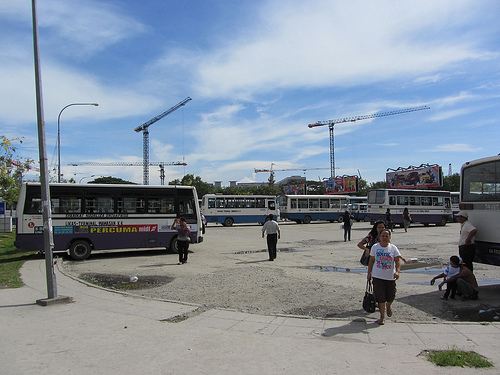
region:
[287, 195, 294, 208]
window on side of bus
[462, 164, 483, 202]
window on side of bus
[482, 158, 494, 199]
window on side of bus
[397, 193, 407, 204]
window on side of bus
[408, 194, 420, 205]
window on side of bus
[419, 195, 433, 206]
window on side of bus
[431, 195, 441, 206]
window on side of bus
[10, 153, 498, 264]
busses parked in lot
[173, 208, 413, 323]
people walking in parking lot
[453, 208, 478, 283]
person standing behind bus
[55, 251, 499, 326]
curb is curved and broken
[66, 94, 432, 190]
large boom cranes above busses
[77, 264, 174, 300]
dried up water spot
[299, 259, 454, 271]
puddle of water by squaters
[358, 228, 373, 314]
two large purses being carried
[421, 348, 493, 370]
small patch of grass in sidewalk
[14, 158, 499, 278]
buses in a parking lot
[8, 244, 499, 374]
sidewalk along parking lot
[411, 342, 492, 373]
grass patch on sidewalk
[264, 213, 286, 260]
man wearing black pants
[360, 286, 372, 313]
black purse woman is carrying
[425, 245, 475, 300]
person kneeling down with child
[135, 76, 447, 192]
construction cranes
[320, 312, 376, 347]
shadow of the woman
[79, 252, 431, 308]
puddles of water in the parking lot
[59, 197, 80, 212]
window on side of bus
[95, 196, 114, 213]
window on side of bus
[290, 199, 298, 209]
window on side of bus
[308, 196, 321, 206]
window on side of bus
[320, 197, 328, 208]
window on side of bus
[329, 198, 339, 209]
window on side of bus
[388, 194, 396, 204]
window on side of bus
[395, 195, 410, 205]
window on side of bus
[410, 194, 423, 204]
window on side of bus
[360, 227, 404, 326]
person carrying a purse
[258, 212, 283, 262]
walking man wearing white shirt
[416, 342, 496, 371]
square of grass in a sidewalk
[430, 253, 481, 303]
man behind a young boy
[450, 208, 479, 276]
man standing with his hands on his hips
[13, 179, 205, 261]
white and grey bus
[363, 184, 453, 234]
two people walking near a bus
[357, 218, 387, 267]
woman holding a purse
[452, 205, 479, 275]
man wearing a white hat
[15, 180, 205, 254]
A bus with yellow letters on side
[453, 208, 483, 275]
man leaning on the side of the bus